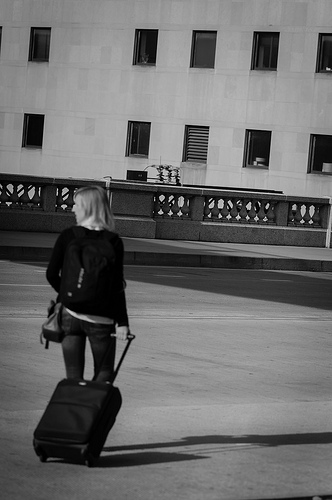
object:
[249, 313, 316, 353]
ground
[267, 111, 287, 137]
ground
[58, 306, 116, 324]
shirt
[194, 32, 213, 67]
glass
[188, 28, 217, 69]
square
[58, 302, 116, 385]
jeans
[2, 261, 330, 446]
street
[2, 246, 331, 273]
curb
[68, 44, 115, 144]
wall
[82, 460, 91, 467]
wheel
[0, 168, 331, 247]
decorative wall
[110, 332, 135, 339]
luggage handle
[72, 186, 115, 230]
blonde hair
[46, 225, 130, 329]
jacket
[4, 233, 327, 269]
sidewalk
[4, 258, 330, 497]
asphalt road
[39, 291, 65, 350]
bag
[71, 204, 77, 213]
nose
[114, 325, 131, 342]
hand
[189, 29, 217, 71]
building window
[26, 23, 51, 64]
building window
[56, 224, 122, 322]
backpack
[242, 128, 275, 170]
window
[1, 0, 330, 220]
building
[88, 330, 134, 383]
handle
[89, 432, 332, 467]
shadow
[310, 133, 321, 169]
glass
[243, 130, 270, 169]
glass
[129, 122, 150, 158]
glass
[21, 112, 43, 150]
glass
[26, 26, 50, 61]
glass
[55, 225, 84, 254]
shoulder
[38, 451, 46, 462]
wheel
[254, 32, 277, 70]
window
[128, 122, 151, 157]
window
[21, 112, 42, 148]
window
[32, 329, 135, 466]
bag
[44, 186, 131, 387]
woman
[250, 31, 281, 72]
blinds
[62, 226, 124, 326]
back